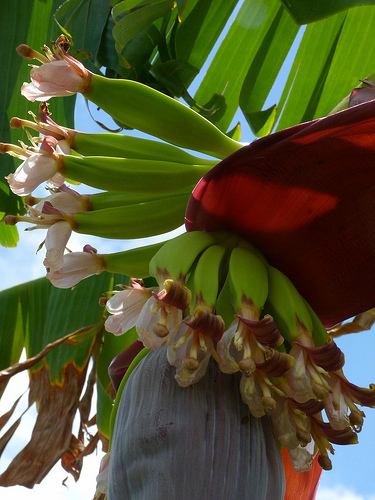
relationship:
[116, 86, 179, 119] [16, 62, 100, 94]
stem of flower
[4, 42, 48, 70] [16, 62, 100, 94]
bulb on flower